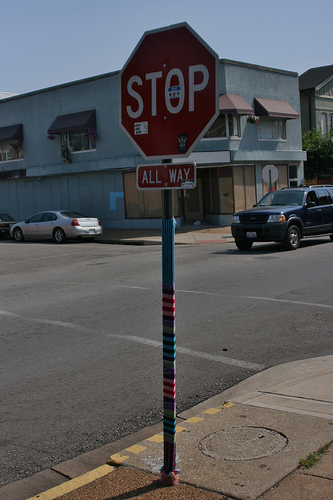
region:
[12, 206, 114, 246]
silver car parked on street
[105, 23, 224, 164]
eight sided traffic sign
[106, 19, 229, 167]
eight sided stop sign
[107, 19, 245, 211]
red traffic sign on post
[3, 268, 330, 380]
pedestrian crosswalk on road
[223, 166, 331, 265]
four door navy blue car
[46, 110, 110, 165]
window on side of building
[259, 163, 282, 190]
eight sided traffic sign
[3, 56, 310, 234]
blue rectangular building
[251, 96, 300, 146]
window on side of building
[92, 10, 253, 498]
stop sign on a pole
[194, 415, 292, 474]
sewer cap in sidewalk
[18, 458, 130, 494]
yellow painted line on sidewalk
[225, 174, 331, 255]
truck driving in the road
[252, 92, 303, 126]
awning of a building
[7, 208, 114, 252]
silver car parked by sidewalk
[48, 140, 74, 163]
plants on a window sill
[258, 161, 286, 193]
back of a stop sign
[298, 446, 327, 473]
patch of weeds in concrete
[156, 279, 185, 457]
decorations on a stop sign pole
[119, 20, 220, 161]
A stop sign on a sidewalk.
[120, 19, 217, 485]
A stop sign on a side of a road.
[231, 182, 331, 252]
A dark colored car.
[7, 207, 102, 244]
A car parked on a street.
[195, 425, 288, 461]
A round manhole.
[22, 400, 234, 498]
A painted sidewalk.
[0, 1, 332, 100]
A blue sky.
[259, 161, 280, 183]
Back of a stop sign.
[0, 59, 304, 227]
A building on the side of road.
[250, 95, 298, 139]
A window with a red shade.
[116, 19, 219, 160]
stop sign on a street corner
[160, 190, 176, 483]
pole holding up stop sign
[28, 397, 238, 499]
yellow paint on the curb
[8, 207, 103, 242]
light colored car parked on street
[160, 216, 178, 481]
different colors of yarn on the pole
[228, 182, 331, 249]
blue ford at he intersection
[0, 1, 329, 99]
blue blue sky over the top of buildings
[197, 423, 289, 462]
metal cover for checking utilities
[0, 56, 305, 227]
blue building on the corner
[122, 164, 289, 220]
paper covering the windows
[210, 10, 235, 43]
white clouds in blue sky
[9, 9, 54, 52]
white clouds in blue sky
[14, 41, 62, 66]
white clouds in blue sky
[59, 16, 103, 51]
white clouds in blue sky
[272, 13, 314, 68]
white clouds in blue sky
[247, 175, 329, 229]
black truck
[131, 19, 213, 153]
red and white street sign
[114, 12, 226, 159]
red and white street stop sign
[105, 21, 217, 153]
white and red street stop sign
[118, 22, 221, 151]
white and red stop sign